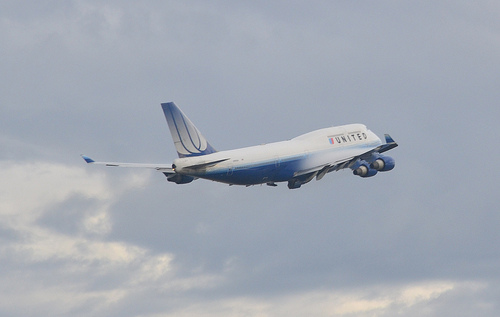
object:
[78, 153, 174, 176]
tail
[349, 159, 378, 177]
engines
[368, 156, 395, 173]
engines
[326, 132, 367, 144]
letters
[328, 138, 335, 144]
symbol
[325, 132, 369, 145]
windows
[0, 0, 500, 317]
sky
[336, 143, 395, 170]
wing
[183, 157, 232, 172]
tail-wing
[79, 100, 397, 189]
plane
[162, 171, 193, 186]
engines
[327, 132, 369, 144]
word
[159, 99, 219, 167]
tail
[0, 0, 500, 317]
clouds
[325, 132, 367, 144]
writing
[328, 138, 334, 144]
symbol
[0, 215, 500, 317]
section